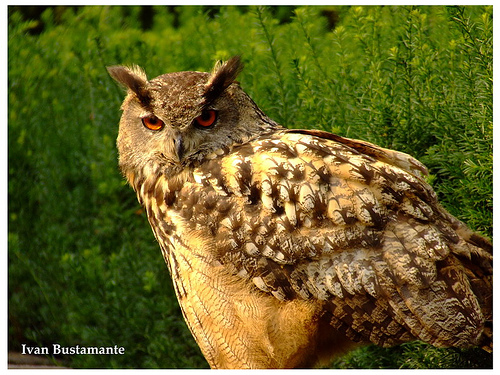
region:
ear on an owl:
[195, 55, 240, 91]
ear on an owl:
[105, 45, 156, 101]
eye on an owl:
[187, 100, 234, 135]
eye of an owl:
[132, 106, 164, 131]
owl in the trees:
[92, 52, 470, 357]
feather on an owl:
[352, 226, 479, 347]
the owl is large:
[104, 52, 496, 373]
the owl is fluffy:
[104, 52, 498, 370]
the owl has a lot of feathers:
[104, 53, 496, 372]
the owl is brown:
[107, 55, 497, 372]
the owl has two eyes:
[107, 54, 494, 369]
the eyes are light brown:
[142, 108, 217, 130]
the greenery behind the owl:
[9, 5, 493, 368]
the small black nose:
[174, 137, 184, 160]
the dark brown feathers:
[106, 56, 492, 368]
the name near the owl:
[7, 5, 492, 373]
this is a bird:
[64, 44, 456, 279]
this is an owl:
[72, 33, 457, 320]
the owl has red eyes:
[71, 64, 279, 165]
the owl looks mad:
[90, 78, 255, 183]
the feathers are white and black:
[201, 147, 439, 335]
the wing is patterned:
[222, 153, 357, 241]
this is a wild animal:
[81, 18, 426, 355]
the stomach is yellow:
[171, 265, 298, 373]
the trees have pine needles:
[267, 31, 492, 123]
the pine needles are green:
[298, 31, 492, 148]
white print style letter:
[21, 342, 28, 356]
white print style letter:
[24, 345, 34, 355]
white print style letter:
[33, 345, 40, 356]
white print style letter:
[39, 345, 49, 357]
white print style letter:
[51, 340, 62, 359]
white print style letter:
[58, 346, 69, 355]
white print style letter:
[67, 346, 77, 353]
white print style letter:
[72, 340, 81, 359]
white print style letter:
[78, 343, 85, 359]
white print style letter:
[83, 344, 104, 358]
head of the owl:
[73, 43, 284, 178]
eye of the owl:
[189, 86, 237, 134]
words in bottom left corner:
[13, 301, 149, 368]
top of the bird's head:
[132, 62, 209, 144]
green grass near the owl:
[18, 168, 129, 275]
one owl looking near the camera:
[36, 43, 466, 326]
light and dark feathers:
[236, 127, 423, 265]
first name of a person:
[8, 326, 58, 373]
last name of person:
[48, 324, 130, 369]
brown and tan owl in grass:
[94, 43, 490, 368]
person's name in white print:
[11, 339, 132, 366]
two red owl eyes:
[131, 106, 221, 140]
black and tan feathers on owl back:
[165, 121, 494, 358]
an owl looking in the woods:
[21, 23, 467, 372]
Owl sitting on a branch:
[99, 45, 489, 361]